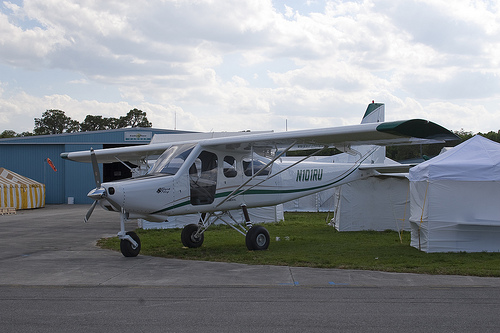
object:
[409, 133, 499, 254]
tent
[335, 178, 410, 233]
tent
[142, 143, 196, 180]
window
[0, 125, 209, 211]
garage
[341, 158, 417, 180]
tail